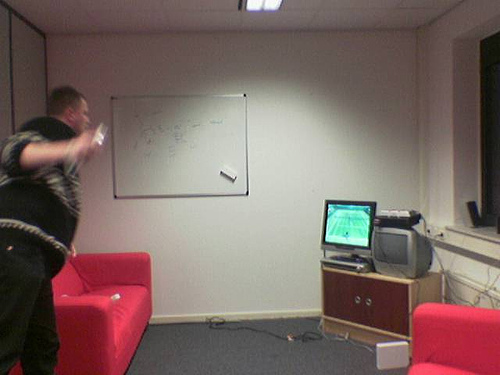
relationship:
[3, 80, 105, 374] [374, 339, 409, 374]
man playing wii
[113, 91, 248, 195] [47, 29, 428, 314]
board on wall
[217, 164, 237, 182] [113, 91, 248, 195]
eraser for board